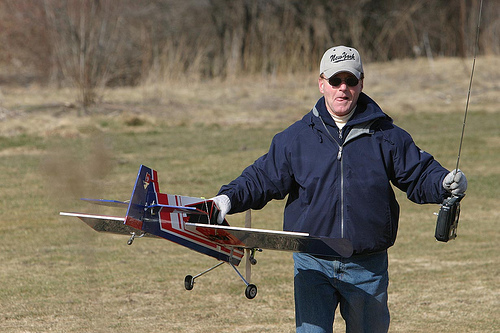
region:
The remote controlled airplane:
[54, 162, 352, 309]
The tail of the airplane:
[76, 159, 207, 225]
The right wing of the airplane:
[189, 219, 356, 262]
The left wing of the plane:
[57, 208, 170, 241]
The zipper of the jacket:
[332, 144, 353, 252]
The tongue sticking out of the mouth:
[330, 92, 350, 104]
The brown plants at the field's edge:
[1, 0, 495, 88]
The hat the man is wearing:
[316, 41, 370, 87]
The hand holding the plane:
[204, 192, 231, 227]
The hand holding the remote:
[441, 166, 470, 200]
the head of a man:
[310, 40, 370, 117]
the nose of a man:
[334, 78, 351, 93]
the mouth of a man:
[331, 91, 351, 106]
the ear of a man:
[311, 72, 327, 97]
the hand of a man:
[439, 165, 474, 201]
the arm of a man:
[373, 117, 450, 209]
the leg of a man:
[340, 251, 399, 331]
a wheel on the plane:
[179, 267, 202, 293]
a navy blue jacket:
[218, 86, 454, 260]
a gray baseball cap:
[312, 40, 374, 87]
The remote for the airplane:
[431, 1, 488, 245]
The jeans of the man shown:
[286, 245, 393, 332]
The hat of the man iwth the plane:
[317, 41, 369, 85]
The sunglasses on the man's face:
[326, 72, 361, 90]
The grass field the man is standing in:
[0, 57, 497, 328]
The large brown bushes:
[0, 0, 496, 92]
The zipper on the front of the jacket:
[336, 140, 346, 239]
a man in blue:
[298, 101, 490, 303]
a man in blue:
[245, 122, 325, 257]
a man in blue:
[261, 104, 345, 326]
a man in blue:
[301, 151, 381, 316]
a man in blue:
[298, 171, 350, 279]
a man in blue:
[197, 31, 351, 312]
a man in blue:
[308, 248, 333, 326]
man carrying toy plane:
[74, 9, 479, 321]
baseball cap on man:
[304, 37, 374, 94]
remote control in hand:
[437, 46, 487, 259]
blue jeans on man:
[288, 251, 397, 331]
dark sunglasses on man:
[321, 73, 360, 91]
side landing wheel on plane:
[235, 281, 262, 305]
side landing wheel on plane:
[182, 275, 201, 295]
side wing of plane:
[221, 221, 316, 261]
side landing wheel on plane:
[65, 209, 124, 242]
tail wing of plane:
[123, 162, 163, 241]